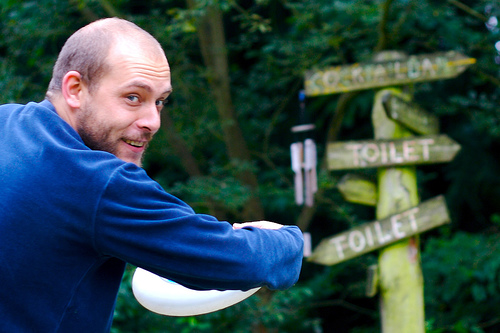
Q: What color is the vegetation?
A: Green.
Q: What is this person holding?
A: A frisbee.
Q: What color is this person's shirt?
A: Blue.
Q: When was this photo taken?
A: Outside, during the daytime.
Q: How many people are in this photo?
A: One.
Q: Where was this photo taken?
A: Near a sign pole.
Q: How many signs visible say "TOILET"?
A: Two.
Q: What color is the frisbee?
A: White.